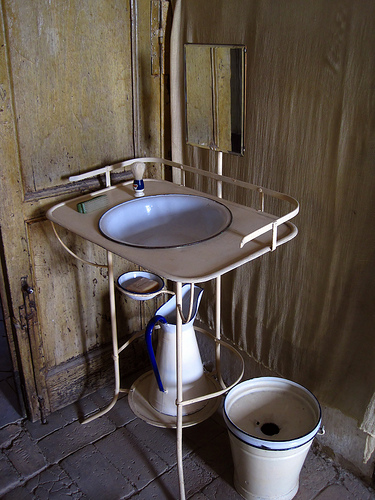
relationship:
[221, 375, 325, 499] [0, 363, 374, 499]
pail on floor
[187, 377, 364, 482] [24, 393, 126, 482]
pail on floor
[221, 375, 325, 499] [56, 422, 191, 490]
pail on floor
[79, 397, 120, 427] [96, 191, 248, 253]
support holding sink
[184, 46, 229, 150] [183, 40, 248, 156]
wall reflected in mirror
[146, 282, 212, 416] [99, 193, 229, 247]
pitcher under sink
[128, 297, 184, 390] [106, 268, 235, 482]
handle on pitcher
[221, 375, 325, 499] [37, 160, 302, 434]
pail by sink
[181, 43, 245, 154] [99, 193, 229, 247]
mirror above sink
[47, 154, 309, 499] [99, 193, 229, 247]
stand on sink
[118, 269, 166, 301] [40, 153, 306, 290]
soap dish under sink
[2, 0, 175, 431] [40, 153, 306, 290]
wall by sink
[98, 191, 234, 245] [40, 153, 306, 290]
sink in sink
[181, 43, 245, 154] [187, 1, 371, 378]
mirror on wall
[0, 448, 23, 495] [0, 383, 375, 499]
brick on floor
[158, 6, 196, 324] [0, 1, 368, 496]
corner in room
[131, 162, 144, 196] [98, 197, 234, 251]
faucet on sink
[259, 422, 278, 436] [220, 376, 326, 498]
hole in bucket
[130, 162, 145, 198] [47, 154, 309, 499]
faucet on stand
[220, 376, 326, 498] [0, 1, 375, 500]
bucket in room